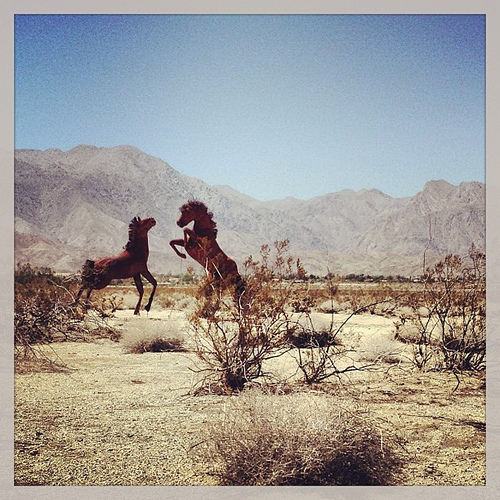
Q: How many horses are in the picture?
A: Two.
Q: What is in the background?
A: Mountains.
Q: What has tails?
A: Two horses.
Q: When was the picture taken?
A: Daytime.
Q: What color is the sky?
A: Blue.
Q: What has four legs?
A: Horses.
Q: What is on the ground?
A: Dirt.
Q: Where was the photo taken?
A: Desert.